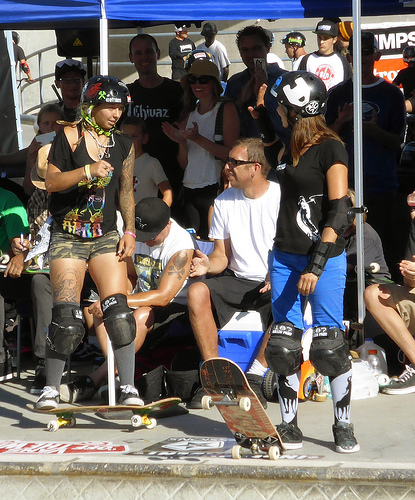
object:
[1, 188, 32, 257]
shirt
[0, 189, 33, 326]
person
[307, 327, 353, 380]
kneepad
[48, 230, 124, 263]
camo shorts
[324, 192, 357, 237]
pads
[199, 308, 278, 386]
cooler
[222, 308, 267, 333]
white lid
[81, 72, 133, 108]
helmet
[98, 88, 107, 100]
sticker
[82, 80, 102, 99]
sticker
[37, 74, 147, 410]
she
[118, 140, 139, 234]
tattoos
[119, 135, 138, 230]
arm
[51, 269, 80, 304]
tattoo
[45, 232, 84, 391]
leg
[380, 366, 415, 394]
shoe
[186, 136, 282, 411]
he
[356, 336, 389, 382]
gallon jug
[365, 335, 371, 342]
blue lid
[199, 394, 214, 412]
wheels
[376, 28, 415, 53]
mps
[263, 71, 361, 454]
girl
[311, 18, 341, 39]
cap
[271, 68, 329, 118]
helmet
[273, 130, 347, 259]
shirt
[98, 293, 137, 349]
knee pad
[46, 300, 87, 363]
knee pad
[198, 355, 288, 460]
skateboard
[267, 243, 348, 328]
pants